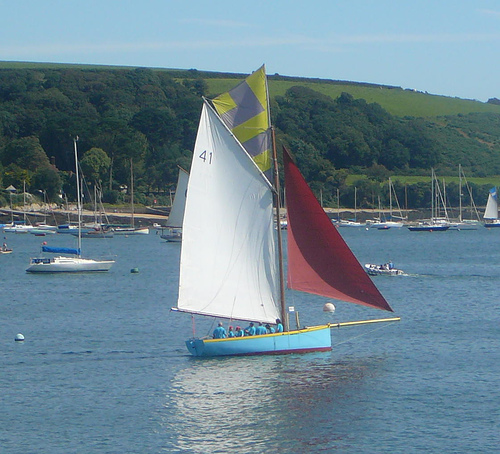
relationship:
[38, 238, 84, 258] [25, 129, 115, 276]
blue mast on boat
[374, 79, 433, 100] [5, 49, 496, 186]
houses on mountain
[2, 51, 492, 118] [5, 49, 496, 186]
top on mountain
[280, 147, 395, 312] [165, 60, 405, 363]
red sail on boat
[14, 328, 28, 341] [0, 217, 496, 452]
bobber in water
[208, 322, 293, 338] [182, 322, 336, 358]
people sitting in boat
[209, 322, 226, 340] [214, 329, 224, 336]
group has shirt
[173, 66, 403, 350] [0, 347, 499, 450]
boat in water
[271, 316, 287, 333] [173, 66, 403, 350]
people in boat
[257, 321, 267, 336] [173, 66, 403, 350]
people in boat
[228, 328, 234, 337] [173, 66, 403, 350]
people in boat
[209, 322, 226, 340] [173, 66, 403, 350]
group in boat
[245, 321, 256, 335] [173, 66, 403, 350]
people in boat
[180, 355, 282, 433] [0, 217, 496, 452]
reflection in water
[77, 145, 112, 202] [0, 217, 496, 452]
tree beyond water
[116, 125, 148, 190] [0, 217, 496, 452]
tree beyond water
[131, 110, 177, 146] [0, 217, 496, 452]
tree beyond water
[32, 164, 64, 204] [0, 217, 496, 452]
tree beyond water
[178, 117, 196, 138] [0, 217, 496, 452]
tree beyond water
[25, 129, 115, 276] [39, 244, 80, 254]
boat without blue mast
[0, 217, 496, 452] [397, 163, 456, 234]
water with boat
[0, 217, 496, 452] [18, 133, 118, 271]
water with boat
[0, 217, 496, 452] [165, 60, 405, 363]
water with boat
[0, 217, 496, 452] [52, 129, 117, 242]
water with boat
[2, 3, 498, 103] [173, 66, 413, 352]
sky above boat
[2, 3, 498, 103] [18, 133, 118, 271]
sky above boat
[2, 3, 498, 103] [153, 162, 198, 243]
sky above boat